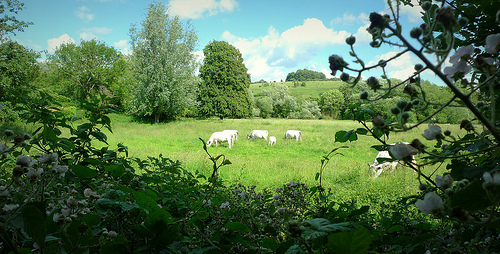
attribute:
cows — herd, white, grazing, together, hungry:
[206, 127, 308, 156]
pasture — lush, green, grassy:
[56, 116, 469, 203]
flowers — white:
[13, 132, 94, 225]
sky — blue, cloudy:
[3, 0, 492, 81]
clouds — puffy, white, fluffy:
[227, 17, 338, 74]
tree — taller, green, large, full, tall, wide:
[127, 1, 195, 126]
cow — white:
[200, 129, 235, 151]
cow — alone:
[366, 142, 420, 179]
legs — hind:
[225, 137, 235, 150]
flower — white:
[386, 133, 423, 167]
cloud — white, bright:
[166, 1, 232, 22]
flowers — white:
[391, 30, 500, 158]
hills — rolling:
[244, 81, 356, 101]